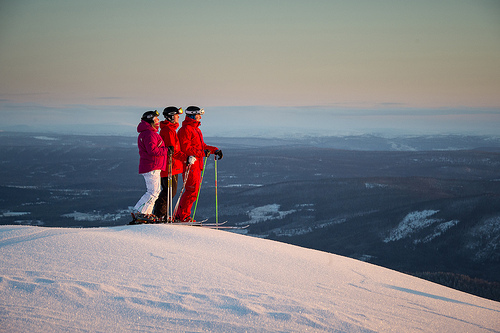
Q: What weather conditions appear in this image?
A: It is cloudy.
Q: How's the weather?
A: It is cloudy.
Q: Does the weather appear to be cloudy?
A: Yes, it is cloudy.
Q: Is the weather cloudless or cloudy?
A: It is cloudy.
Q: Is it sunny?
A: No, it is cloudy.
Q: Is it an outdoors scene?
A: Yes, it is outdoors.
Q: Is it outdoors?
A: Yes, it is outdoors.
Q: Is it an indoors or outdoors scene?
A: It is outdoors.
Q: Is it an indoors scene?
A: No, it is outdoors.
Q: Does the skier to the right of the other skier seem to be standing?
A: Yes, the skier is standing.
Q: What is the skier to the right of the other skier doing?
A: The skier is standing.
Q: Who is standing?
A: The skier is standing.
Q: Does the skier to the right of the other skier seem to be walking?
A: No, the skier is standing.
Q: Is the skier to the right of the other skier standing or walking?
A: The skier is standing.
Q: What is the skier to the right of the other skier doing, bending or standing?
A: The skier is standing.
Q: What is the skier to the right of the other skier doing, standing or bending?
A: The skier is standing.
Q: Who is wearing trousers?
A: The skier is wearing trousers.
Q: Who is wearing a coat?
A: The skier is wearing a coat.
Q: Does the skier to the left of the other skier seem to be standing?
A: Yes, the skier is standing.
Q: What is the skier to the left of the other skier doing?
A: The skier is standing.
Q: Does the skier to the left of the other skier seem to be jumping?
A: No, the skier is standing.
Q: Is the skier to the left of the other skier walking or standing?
A: The skier is standing.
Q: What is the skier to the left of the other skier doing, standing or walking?
A: The skier is standing.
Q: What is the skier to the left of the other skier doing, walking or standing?
A: The skier is standing.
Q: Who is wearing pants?
A: The skier is wearing pants.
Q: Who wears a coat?
A: The skier wears a coat.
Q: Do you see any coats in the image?
A: Yes, there is a coat.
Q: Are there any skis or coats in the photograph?
A: Yes, there is a coat.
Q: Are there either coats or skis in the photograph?
A: Yes, there is a coat.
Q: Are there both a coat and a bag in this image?
A: No, there is a coat but no bags.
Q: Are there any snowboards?
A: No, there are no snowboards.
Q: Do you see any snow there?
A: Yes, there is snow.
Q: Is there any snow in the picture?
A: Yes, there is snow.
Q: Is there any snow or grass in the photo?
A: Yes, there is snow.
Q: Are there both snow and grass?
A: No, there is snow but no grass.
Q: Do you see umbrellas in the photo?
A: No, there are no umbrellas.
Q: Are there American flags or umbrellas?
A: No, there are no umbrellas or American flags.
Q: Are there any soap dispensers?
A: No, there are no soap dispensers.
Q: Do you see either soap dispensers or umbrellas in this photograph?
A: No, there are no soap dispensers or umbrellas.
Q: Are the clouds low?
A: Yes, the clouds are low.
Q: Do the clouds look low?
A: Yes, the clouds are low.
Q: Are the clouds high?
A: No, the clouds are low.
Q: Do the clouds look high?
A: No, the clouds are low.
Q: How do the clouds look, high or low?
A: The clouds are low.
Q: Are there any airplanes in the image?
A: No, there are no airplanes.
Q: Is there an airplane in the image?
A: No, there are no airplanes.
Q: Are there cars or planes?
A: No, there are no planes or cars.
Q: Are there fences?
A: No, there are no fences.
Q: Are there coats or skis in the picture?
A: Yes, there is a coat.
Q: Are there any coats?
A: Yes, there is a coat.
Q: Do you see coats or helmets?
A: Yes, there is a coat.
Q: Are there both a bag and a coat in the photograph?
A: No, there is a coat but no bags.